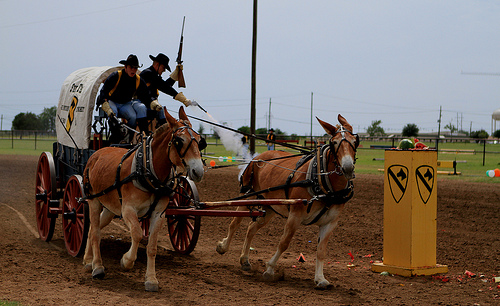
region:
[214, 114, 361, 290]
the horse on the right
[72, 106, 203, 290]
the horse on the left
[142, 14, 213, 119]
a man shooting two guns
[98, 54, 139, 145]
a man steering the horses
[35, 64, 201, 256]
a covered wagon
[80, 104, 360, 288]
two horses pulling a wagon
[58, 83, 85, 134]
logo on the side of the wagon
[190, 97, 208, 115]
a pistol being shot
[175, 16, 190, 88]
a shotgun in the air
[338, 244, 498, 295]
debris on the ground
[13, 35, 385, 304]
two mules pulling a wagon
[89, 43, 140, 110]
a man wearing a cowboy hat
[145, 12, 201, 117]
a man holding two guns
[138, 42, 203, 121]
a man firing a gun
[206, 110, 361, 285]
a mule running on a dirt track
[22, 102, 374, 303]
two mules running on a dirt track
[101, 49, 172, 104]
two men wearing cowboy hats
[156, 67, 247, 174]
smoke coming from a gun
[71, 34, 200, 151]
two men riding in a wagon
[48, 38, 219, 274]
two men in a wagon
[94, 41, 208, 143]
two men on a wagon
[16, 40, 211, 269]
the wagon is wooden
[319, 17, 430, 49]
the sky is gray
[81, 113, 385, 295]
the horses attached to the wagon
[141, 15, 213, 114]
the man firing the pistol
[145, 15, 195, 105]
the man holding the rifle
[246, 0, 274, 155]
the pole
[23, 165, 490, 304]
the dirt on the track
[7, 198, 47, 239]
the wheel tracks behind the wagon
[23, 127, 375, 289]
the horses are brown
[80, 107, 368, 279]
a pair of mules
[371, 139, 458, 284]
a large yellow pole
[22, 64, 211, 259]
an old covered wagon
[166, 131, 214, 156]
a pair of blinders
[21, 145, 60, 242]
a large red wheel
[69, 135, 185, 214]
a black leather harness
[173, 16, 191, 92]
rifle with a wood stock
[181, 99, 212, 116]
a silver six shooter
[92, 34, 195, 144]
a pair of guys wearing costumes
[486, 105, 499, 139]
a distant water tower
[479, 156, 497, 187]
balloons on the grass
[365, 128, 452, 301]
yellow stand on the track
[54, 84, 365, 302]
two horses pulling the wagon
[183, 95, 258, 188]
gun is firing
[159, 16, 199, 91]
man is holding a rifle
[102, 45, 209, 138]
two men driving the wagon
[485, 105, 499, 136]
water tower in the back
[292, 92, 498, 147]
power lines behind the men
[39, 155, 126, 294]
wheels are red and black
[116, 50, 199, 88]
men are wearing black hats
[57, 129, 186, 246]
a horse in harness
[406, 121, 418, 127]
green leaves on the tree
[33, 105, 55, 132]
green leaves on the tree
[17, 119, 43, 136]
green leaves on the tree